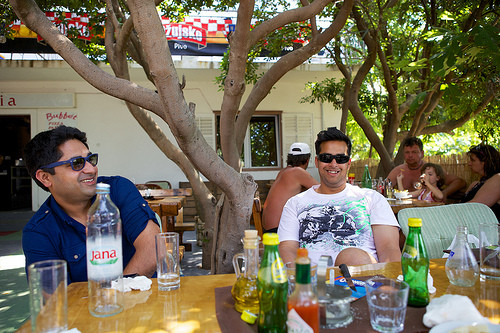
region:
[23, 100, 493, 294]
people sitting around tables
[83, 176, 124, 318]
empty bottle of water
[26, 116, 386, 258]
two men wearing sunglasses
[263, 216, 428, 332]
two green bottles with yellow caps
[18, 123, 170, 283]
man wearing blue shirt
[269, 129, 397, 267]
man wearing white shirt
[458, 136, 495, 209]
woman in the background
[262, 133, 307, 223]
shirtless man wearing white hat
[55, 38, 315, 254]
tree trunk between two men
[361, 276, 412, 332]
glass stting on table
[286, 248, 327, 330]
glass hot sauce bottle on table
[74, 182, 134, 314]
clear plastic water bottle on table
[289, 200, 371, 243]
design on front of shirt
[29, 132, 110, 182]
man in blue sunglasses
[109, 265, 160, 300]
white napkin laying on table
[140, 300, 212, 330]
sun shining on wooden table top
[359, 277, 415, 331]
clear drinking glass on table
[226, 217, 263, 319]
clear glass bottle of olive oil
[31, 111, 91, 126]
sign on side of building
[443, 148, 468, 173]
brown wooden picket fence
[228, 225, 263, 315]
small bottle of oil on a table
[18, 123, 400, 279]
two men sitting at a table together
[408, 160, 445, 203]
child drinking out of a glass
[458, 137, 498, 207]
woman seated next to a child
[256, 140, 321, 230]
seated man not wearing a shirt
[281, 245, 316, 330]
bottle of orange colored hot sauce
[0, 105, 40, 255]
entryway into a restaurant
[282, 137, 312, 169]
back of a white baseball cap on a man's head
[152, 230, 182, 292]
tall empty drinking glass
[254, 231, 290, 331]
green glass bottle with yellow cap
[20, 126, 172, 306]
A man sitting at a table with a blue shirt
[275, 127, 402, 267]
A man sitting at a table wearing a mostly white shirt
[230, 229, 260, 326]
Most of a bottle of oil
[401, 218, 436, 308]
A green clear bottle with a yellow cap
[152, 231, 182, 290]
A clear empty glass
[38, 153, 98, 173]
A pair of blue sunglasses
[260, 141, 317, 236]
Part of a man without a shirt wearing a white hat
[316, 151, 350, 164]
A pair of black sunglasses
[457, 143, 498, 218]
Part of a woman wearing sunglasses on her head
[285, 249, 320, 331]
Part of a bottle of tobasco sauce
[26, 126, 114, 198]
A man wearing sunglasses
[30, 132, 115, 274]
A man with black hair and a blue shirt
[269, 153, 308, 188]
A man with no shirt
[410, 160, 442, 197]
A little girl drinking from a can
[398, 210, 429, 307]
A green bottle with a yellow lid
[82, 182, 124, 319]
A tall bottle of water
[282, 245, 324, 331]
A bottle of Tabsco sauce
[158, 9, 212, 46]
A sign in a foreign language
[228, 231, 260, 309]
A cruet with oil in it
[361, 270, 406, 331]
A small empty tumbler